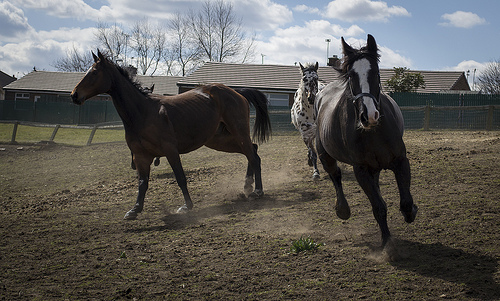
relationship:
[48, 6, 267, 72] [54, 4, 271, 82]
trees with no leaves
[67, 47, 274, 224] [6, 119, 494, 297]
horse on a field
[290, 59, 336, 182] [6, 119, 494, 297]
horse on a field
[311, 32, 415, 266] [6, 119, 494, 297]
horse on a field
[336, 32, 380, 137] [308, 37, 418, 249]
head of horse